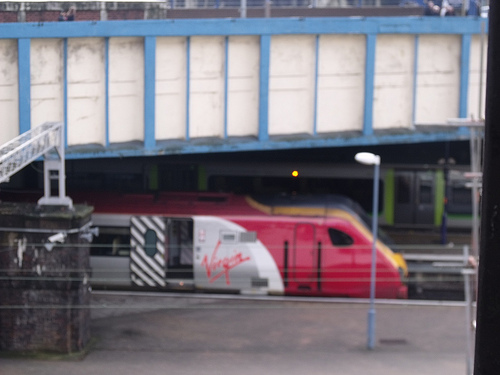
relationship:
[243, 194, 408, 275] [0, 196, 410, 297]
stripe on train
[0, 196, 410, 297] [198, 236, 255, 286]
train says virgin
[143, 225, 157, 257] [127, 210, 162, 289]
window on door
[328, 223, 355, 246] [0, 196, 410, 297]
window on train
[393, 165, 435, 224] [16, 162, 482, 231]
doors on train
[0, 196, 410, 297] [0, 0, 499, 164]
train underneath bridge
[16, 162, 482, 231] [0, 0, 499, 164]
train underneath bridge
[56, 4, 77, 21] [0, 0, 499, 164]
person on bridge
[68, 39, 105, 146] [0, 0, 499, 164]
panel on bridge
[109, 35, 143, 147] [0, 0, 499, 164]
panel on bridge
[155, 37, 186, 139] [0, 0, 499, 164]
panel on bridge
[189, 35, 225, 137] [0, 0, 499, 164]
panel on bridge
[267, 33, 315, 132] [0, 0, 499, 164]
panel on bridge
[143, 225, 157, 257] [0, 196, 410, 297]
oval window on train